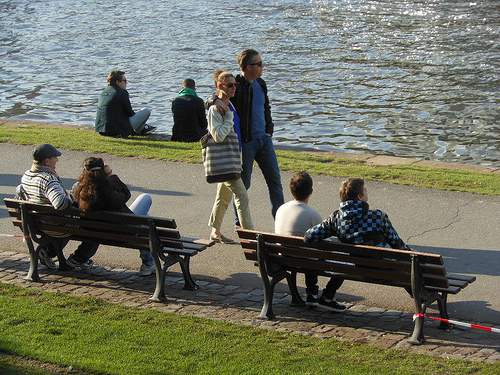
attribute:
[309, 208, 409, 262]
sweater — plaid, blue, black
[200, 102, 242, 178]
purse — gray, white, striped, oversized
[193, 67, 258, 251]
woman — walking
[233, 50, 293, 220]
man — walking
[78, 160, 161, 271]
woman — sitting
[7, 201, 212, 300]
bench — brown, wooden, slatted, wood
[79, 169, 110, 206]
hair — dark, long, brown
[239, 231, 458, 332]
bench — wooden, brown, wood, slatted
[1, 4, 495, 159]
lake — here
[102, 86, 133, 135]
jacket — black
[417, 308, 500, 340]
tape — red, white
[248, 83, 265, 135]
shirt — blue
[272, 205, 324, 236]
shirt — white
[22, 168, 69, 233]
jacket — striped